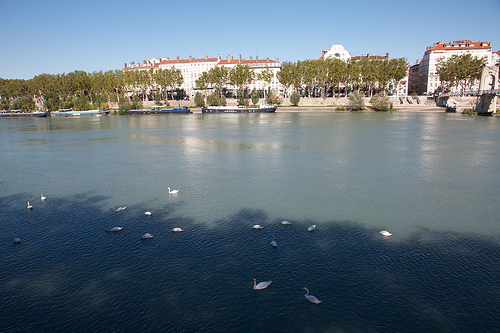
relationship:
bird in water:
[378, 224, 399, 243] [9, 112, 499, 331]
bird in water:
[301, 284, 321, 304] [9, 112, 499, 331]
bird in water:
[250, 221, 267, 232] [9, 112, 499, 331]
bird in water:
[170, 223, 183, 235] [9, 112, 499, 331]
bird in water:
[162, 185, 179, 195] [211, 114, 495, 235]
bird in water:
[100, 224, 124, 234] [48, 254, 279, 295]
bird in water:
[140, 230, 152, 240] [9, 112, 499, 331]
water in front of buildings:
[9, 112, 499, 331] [121, 40, 483, 110]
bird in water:
[37, 191, 49, 202] [9, 112, 499, 331]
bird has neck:
[301, 287, 323, 304] [166, 187, 174, 197]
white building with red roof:
[122, 63, 292, 98] [123, 52, 282, 71]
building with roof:
[417, 39, 494, 94] [426, 37, 492, 52]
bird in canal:
[301, 287, 323, 304] [1, 115, 498, 330]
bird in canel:
[379, 230, 393, 237] [367, 202, 413, 281]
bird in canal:
[166, 187, 179, 195] [145, 129, 409, 191]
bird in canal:
[253, 278, 272, 291] [145, 129, 409, 191]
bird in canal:
[301, 287, 323, 304] [145, 129, 409, 191]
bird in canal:
[379, 230, 393, 237] [145, 129, 409, 191]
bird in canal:
[140, 233, 153, 240] [145, 129, 409, 191]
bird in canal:
[105, 226, 123, 232] [1, 115, 498, 330]